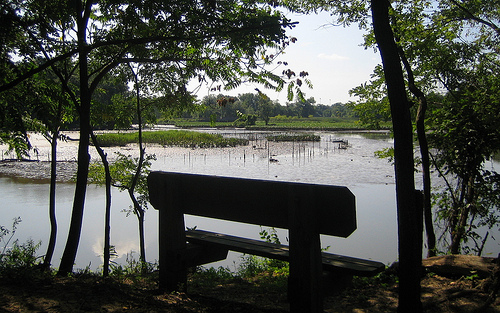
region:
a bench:
[135, 170, 383, 290]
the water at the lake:
[338, 153, 372, 186]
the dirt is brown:
[68, 284, 113, 302]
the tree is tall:
[56, 19, 100, 279]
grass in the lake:
[166, 127, 226, 145]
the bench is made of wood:
[333, 252, 374, 276]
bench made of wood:
[138, 159, 390, 304]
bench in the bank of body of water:
[134, 151, 398, 305]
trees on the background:
[166, 81, 391, 136]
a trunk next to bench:
[123, 7, 498, 311]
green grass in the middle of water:
[88, 119, 248, 154]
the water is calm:
[174, 149, 359, 172]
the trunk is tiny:
[119, 68, 156, 270]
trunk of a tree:
[368, 1, 430, 311]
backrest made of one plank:
[140, 162, 372, 257]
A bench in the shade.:
[140, 165, 405, 295]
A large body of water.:
[46, 117, 443, 207]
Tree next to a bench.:
[5, 8, 143, 276]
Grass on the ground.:
[0, 244, 148, 289]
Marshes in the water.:
[93, 115, 255, 152]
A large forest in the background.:
[214, 91, 402, 121]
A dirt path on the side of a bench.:
[386, 255, 497, 307]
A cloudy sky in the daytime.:
[192, 15, 416, 87]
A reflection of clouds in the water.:
[86, 180, 153, 267]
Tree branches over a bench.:
[167, 45, 335, 105]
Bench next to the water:
[142, 168, 384, 302]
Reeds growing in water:
[181, 135, 342, 162]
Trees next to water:
[1, 0, 150, 274]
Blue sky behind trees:
[173, 0, 380, 124]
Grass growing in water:
[84, 128, 249, 150]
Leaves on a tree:
[147, 55, 314, 101]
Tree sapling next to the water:
[116, 68, 154, 279]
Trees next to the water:
[365, 0, 498, 309]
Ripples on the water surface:
[146, 138, 395, 185]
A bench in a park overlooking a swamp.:
[138, 158, 388, 306]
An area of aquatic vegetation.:
[77, 119, 262, 156]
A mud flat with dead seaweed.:
[5, 150, 124, 188]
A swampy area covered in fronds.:
[174, 102, 404, 137]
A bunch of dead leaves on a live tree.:
[202, 77, 246, 112]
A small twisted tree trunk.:
[387, 37, 445, 265]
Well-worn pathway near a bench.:
[8, 252, 498, 311]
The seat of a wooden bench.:
[178, 224, 391, 281]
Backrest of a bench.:
[140, 169, 362, 243]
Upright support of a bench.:
[153, 192, 234, 299]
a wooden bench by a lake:
[108, 95, 463, 298]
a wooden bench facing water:
[19, 58, 426, 290]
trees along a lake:
[11, 5, 250, 301]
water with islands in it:
[28, 41, 455, 286]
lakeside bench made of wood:
[145, 170, 388, 312]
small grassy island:
[88, 129, 249, 149]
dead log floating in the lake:
[331, 139, 348, 143]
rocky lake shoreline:
[1, 255, 496, 310]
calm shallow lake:
[1, 125, 497, 312]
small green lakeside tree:
[427, 60, 498, 255]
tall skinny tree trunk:
[370, 0, 425, 312]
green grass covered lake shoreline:
[148, 120, 391, 132]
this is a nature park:
[43, 50, 445, 295]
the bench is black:
[128, 143, 354, 249]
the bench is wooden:
[160, 123, 363, 263]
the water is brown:
[223, 129, 455, 241]